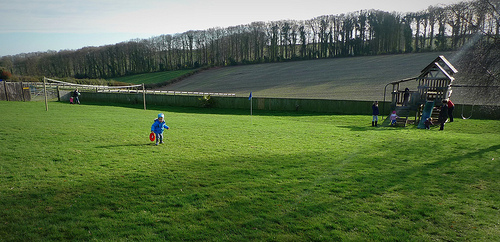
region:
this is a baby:
[145, 97, 173, 147]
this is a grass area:
[219, 132, 317, 213]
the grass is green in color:
[233, 165, 292, 200]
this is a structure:
[404, 62, 441, 121]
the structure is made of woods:
[426, 65, 448, 89]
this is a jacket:
[151, 122, 166, 129]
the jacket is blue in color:
[156, 120, 161, 130]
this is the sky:
[31, 5, 106, 40]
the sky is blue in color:
[17, 10, 53, 43]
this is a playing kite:
[146, 131, 158, 141]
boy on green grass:
[127, 113, 190, 155]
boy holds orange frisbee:
[130, 107, 197, 166]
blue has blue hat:
[152, 110, 173, 120]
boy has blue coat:
[144, 115, 169, 131]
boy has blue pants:
[151, 130, 165, 147]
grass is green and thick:
[209, 140, 278, 220]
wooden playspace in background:
[354, 37, 464, 146]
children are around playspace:
[365, 70, 457, 128]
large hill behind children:
[162, 35, 415, 94]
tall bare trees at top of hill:
[20, 49, 450, 79]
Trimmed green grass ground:
[0, 99, 497, 229]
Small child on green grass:
[143, 110, 193, 166]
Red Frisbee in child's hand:
[146, 118, 161, 143]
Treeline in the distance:
[15, 25, 495, 42]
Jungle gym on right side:
[385, 48, 458, 142]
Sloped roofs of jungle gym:
[413, 56, 457, 89]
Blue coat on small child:
[141, 119, 171, 142]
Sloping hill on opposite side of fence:
[182, 51, 499, 154]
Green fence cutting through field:
[71, 77, 497, 127]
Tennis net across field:
[39, 70, 159, 118]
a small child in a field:
[138, 102, 181, 159]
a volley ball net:
[28, 73, 151, 112]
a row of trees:
[166, 14, 443, 80]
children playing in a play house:
[359, 48, 469, 147]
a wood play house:
[372, 49, 469, 135]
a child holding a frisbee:
[140, 99, 172, 142]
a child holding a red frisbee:
[148, 99, 173, 151]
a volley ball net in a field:
[38, 74, 158, 123]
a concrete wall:
[148, 87, 356, 114]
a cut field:
[198, 39, 409, 91]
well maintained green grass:
[76, 154, 230, 207]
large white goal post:
[30, 69, 148, 116]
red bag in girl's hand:
[138, 126, 166, 147]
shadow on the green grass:
[110, 150, 320, 195]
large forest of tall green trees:
[191, 29, 394, 59]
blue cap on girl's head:
[148, 108, 170, 120]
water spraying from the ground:
[451, 32, 483, 56]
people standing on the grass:
[371, 85, 463, 132]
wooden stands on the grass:
[410, 44, 481, 102]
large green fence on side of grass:
[155, 83, 357, 118]